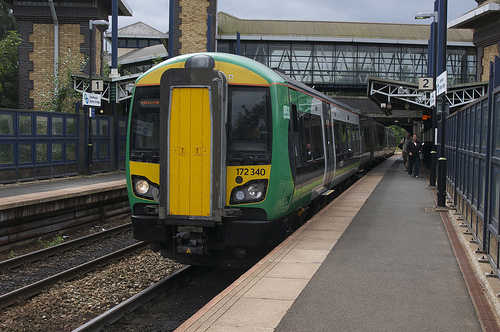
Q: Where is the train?
A: On the tracks.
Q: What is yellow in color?
A: Train.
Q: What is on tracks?
A: Gravel.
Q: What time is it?
A: Afternoon.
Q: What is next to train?
A: Sidewalk.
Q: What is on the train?
A: Windows.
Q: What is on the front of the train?
A: A yellow door.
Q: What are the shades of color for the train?
A: Green and yellow.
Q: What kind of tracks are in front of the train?
A: Long black ones.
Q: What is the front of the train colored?
A: Yellow.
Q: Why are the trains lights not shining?
A: They are off.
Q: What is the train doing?
A: Not moving.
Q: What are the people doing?
A: Walking.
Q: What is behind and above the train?
A: Bridge.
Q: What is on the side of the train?
A: Windows.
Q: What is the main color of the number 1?
A: Black.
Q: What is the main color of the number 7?
A: Black.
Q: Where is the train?
A: On the track.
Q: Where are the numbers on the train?
A: In the front.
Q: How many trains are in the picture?
A: One.